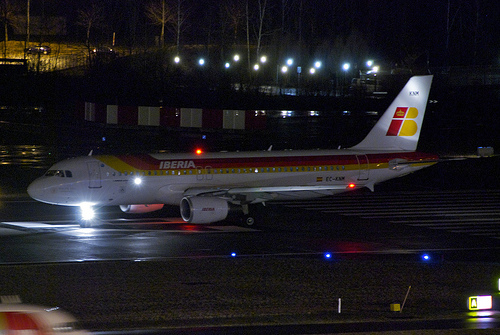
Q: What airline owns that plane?
A: IBERIA.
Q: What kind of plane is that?
A: A large passenger plane.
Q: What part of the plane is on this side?
A: The engine.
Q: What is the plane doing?
A: Driving on the runway?.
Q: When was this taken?
A: During night time.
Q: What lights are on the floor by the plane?
A: Small blue lights.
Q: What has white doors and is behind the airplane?
A: A red building.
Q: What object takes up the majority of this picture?
A: An airplane.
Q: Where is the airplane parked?
A: On the runway.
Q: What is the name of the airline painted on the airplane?
A: IBERIA.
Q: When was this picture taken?
A: At night.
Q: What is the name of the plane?
A: Iberia.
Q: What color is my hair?
A: Brown.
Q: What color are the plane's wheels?
A: Black.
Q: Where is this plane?
A: At an airport.